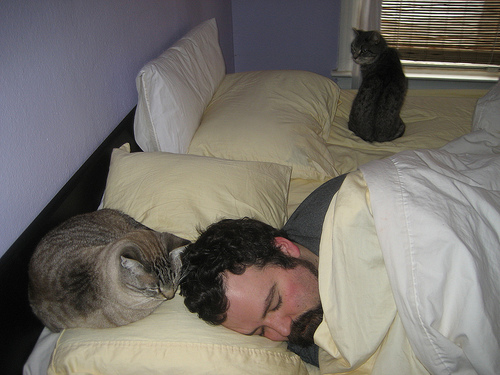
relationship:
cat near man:
[45, 199, 182, 329] [214, 177, 462, 341]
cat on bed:
[45, 199, 182, 329] [168, 60, 499, 312]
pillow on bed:
[199, 65, 325, 177] [168, 60, 499, 312]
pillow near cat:
[199, 65, 325, 177] [45, 199, 182, 329]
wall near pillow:
[49, 17, 110, 68] [199, 65, 325, 177]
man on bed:
[214, 177, 462, 341] [168, 60, 499, 312]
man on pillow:
[214, 177, 462, 341] [199, 65, 325, 177]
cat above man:
[45, 199, 182, 329] [214, 177, 462, 341]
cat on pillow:
[45, 199, 182, 329] [199, 65, 325, 177]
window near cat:
[393, 1, 493, 57] [45, 199, 182, 329]